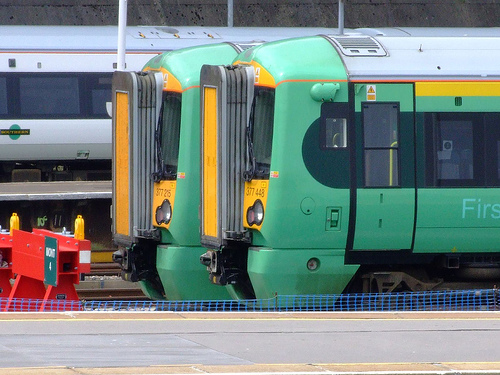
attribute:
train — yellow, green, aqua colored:
[200, 31, 494, 304]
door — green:
[349, 78, 423, 268]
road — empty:
[13, 308, 499, 366]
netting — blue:
[5, 293, 500, 318]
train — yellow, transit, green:
[108, 40, 261, 300]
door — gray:
[110, 68, 164, 248]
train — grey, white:
[4, 22, 500, 193]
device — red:
[1, 211, 105, 320]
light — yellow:
[71, 215, 89, 240]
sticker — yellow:
[367, 84, 378, 95]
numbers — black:
[246, 188, 268, 202]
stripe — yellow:
[421, 76, 500, 101]